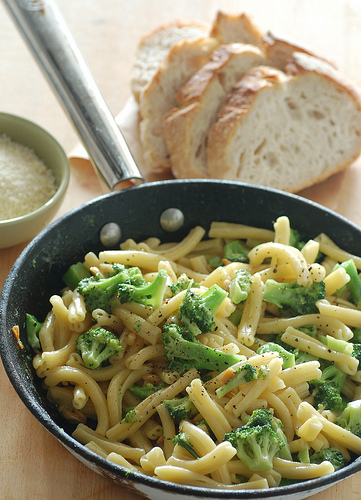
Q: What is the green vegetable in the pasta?
A: Broccoli.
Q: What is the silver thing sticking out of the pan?
A: Handle.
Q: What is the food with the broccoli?
A: Pasta.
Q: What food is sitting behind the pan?
A: Bread.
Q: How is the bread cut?
A: Sliced.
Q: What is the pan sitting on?
A: Table.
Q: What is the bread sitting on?
A: Table.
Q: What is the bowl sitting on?
A: Table.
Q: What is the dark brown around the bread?
A: Crust.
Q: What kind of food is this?
A: Macaroni with broccoli.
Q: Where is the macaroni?
A: In a metal pan.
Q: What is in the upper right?
A: Large slices of bread.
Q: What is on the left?
A: A small white bowl.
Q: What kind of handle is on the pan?
A: A silver colored handle.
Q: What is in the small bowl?
A: White rice.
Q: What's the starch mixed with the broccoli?
A: Pasta.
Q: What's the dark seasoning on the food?
A: Pepper.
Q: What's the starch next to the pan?
A: Bread.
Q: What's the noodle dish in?
A: Pan.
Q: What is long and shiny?
A: Handle on the pan.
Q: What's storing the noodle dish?
A: Pan.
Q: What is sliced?
A: Bread.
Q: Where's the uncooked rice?
A: In small bowl.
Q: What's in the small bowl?
A: Uncooked rice.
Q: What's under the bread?
A: Napkin.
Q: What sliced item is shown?
A: Bread.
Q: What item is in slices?
A: Bread.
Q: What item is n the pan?
A: Pasta.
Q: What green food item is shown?
A: Broccoli.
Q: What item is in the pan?
A: Pasta.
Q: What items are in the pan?
A: Pasta and Vegetables.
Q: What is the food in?
A: A pan.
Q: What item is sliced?
A: Bread.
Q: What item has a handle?
A: A pot.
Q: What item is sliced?
A: Bread.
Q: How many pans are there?
A: One.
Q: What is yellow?
A: Macaroni.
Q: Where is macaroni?
A: On a pan.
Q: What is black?
A: Pan.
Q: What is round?
A: The pan.